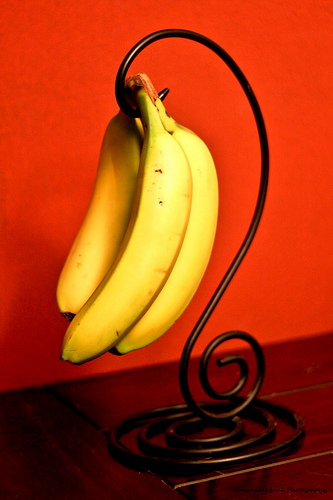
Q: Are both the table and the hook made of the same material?
A: No, the table is made of wood and the hook is made of metal.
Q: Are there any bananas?
A: Yes, there is a banana.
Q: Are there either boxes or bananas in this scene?
A: Yes, there is a banana.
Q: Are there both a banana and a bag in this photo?
A: No, there is a banana but no bags.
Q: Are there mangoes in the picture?
A: No, there are no mangoes.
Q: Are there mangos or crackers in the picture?
A: No, there are no mangos or crackers.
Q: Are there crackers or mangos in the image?
A: No, there are no mangos or crackers.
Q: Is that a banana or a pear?
A: That is a banana.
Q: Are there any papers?
A: No, there are no papers.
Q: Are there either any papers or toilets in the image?
A: No, there are no papers or toilets.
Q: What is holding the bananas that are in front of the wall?
A: The hook is holding the bananas.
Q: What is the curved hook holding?
A: The hook is holding the bananas.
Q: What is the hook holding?
A: The hook is holding the bananas.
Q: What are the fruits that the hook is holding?
A: The fruits are bananas.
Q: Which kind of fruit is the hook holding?
A: The hook is holding the bananas.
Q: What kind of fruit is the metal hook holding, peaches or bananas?
A: The hook is holding bananas.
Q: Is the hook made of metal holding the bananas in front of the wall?
A: Yes, the hook is holding the bananas.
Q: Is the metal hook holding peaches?
A: No, the hook is holding the bananas.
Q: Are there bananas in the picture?
A: Yes, there are bananas.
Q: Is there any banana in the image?
A: Yes, there are bananas.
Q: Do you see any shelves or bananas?
A: Yes, there are bananas.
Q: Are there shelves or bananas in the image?
A: Yes, there are bananas.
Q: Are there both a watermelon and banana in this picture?
A: No, there are bananas but no watermelons.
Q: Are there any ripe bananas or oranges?
A: Yes, there are ripe bananas.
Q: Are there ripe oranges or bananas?
A: Yes, there are ripe bananas.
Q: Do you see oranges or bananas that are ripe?
A: Yes, the bananas are ripe.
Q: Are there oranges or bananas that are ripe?
A: Yes, the bananas are ripe.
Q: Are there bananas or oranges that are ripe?
A: Yes, the bananas are ripe.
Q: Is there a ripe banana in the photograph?
A: Yes, there are ripe bananas.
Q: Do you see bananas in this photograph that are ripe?
A: Yes, there are ripe bananas.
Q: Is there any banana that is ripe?
A: Yes, there are bananas that are ripe.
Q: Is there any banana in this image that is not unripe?
A: Yes, there are ripe bananas.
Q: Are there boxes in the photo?
A: No, there are no boxes.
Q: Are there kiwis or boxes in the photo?
A: No, there are no boxes or kiwis.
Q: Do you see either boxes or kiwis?
A: No, there are no boxes or kiwis.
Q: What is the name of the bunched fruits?
A: The fruits are bananas.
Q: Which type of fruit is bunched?
A: The fruit is bananas.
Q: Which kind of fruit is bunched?
A: The fruit is bananas.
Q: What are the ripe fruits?
A: The fruits are bananas.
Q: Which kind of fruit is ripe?
A: The fruit is bananas.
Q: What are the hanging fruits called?
A: The fruits are bananas.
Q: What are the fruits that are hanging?
A: The fruits are bananas.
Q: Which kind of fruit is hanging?
A: The fruit is bananas.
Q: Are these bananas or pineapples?
A: These are bananas.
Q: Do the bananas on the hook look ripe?
A: Yes, the bananas are ripe.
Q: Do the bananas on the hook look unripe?
A: No, the bananas are ripe.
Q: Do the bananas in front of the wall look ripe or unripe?
A: The bananas are ripe.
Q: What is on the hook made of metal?
A: The bananas are on the hook.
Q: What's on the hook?
A: The bananas are on the hook.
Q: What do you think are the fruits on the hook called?
A: The fruits are bananas.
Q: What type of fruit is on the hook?
A: The fruits are bananas.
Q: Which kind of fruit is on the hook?
A: The fruits are bananas.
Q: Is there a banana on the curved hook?
A: Yes, there are bananas on the hook.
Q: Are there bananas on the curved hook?
A: Yes, there are bananas on the hook.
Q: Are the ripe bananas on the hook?
A: Yes, the bananas are on the hook.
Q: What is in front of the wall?
A: The bananas are in front of the wall.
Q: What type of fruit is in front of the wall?
A: The fruits are bananas.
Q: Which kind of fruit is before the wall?
A: The fruits are bananas.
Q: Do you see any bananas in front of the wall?
A: Yes, there are bananas in front of the wall.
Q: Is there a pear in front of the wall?
A: No, there are bananas in front of the wall.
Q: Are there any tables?
A: Yes, there is a table.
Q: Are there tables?
A: Yes, there is a table.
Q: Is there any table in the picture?
A: Yes, there is a table.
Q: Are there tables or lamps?
A: Yes, there is a table.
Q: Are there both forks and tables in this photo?
A: No, there is a table but no forks.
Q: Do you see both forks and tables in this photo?
A: No, there is a table but no forks.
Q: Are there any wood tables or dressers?
A: Yes, there is a wood table.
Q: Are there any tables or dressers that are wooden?
A: Yes, the table is wooden.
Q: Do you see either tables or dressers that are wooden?
A: Yes, the table is wooden.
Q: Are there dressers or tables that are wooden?
A: Yes, the table is wooden.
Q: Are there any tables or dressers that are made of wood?
A: Yes, the table is made of wood.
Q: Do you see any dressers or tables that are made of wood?
A: Yes, the table is made of wood.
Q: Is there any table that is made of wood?
A: Yes, there is a table that is made of wood.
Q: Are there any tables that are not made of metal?
A: Yes, there is a table that is made of wood.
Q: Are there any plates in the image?
A: No, there are no plates.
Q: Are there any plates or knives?
A: No, there are no plates or knives.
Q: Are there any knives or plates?
A: No, there are no plates or knives.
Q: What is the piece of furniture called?
A: The piece of furniture is a table.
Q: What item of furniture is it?
A: The piece of furniture is a table.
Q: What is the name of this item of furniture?
A: This is a table.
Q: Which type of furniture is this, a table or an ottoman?
A: This is a table.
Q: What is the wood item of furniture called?
A: The piece of furniture is a table.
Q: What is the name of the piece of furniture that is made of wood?
A: The piece of furniture is a table.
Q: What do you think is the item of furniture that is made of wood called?
A: The piece of furniture is a table.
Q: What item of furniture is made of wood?
A: The piece of furniture is a table.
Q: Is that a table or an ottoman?
A: That is a table.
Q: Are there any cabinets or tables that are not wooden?
A: No, there is a table but it is wooden.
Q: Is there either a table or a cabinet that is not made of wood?
A: No, there is a table but it is made of wood.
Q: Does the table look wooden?
A: Yes, the table is wooden.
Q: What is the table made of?
A: The table is made of wood.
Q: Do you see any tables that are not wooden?
A: No, there is a table but it is wooden.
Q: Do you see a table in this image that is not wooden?
A: No, there is a table but it is wooden.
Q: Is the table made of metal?
A: No, the table is made of wood.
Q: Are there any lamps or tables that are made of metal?
A: No, there is a table but it is made of wood.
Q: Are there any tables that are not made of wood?
A: No, there is a table but it is made of wood.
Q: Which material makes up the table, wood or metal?
A: The table is made of wood.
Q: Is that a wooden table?
A: Yes, that is a wooden table.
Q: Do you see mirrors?
A: No, there are no mirrors.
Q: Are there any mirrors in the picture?
A: No, there are no mirrors.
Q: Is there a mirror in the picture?
A: No, there are no mirrors.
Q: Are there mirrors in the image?
A: No, there are no mirrors.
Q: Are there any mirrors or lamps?
A: No, there are no mirrors or lamps.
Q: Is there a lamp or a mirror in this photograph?
A: No, there are no mirrors or lamps.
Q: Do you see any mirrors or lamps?
A: No, there are no mirrors or lamps.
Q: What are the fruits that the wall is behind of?
A: The fruits are bananas.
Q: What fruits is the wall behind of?
A: The wall is behind the bananas.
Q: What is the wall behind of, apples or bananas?
A: The wall is behind bananas.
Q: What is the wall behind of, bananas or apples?
A: The wall is behind bananas.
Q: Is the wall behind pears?
A: No, the wall is behind the bananas.